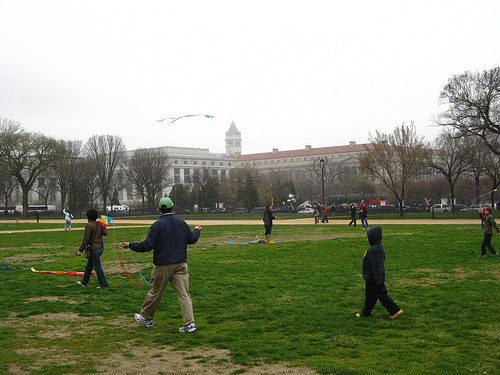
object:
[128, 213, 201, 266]
jacket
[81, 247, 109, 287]
pants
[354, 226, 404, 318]
people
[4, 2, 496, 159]
sky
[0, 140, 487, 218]
building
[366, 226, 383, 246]
cap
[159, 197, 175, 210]
cap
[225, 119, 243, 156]
buildings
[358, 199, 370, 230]
people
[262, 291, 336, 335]
grass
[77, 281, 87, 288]
shoes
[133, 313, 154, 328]
feet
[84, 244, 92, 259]
purse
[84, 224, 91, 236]
shoulder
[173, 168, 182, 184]
window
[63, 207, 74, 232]
person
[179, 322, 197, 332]
shoe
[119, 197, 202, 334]
kite flyers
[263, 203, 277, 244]
kite flyers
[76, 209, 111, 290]
kite flyers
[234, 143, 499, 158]
roof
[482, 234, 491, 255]
leg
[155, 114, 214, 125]
kite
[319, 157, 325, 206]
lamp post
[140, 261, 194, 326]
pants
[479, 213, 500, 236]
shirt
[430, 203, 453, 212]
vehicle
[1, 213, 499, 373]
ground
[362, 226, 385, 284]
hoodie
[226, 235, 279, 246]
kite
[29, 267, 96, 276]
kite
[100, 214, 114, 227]
kite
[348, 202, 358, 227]
person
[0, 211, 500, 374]
field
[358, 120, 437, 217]
tree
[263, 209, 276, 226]
jacket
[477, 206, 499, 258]
boy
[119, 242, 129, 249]
hand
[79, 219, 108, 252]
jacket